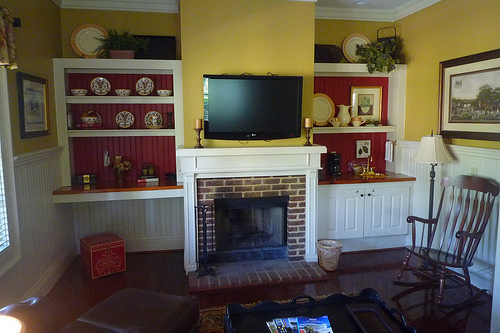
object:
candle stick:
[193, 127, 205, 148]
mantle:
[175, 144, 327, 179]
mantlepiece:
[175, 144, 327, 273]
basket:
[376, 26, 397, 63]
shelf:
[311, 47, 417, 185]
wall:
[386, 0, 499, 155]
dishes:
[62, 67, 176, 131]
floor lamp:
[410, 129, 455, 275]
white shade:
[410, 135, 454, 164]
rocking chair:
[397, 174, 499, 310]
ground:
[410, 134, 454, 163]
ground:
[400, 140, 430, 167]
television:
[203, 74, 304, 140]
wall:
[180, 0, 315, 190]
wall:
[401, 137, 500, 310]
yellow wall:
[186, 7, 306, 68]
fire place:
[196, 175, 306, 263]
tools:
[194, 203, 217, 279]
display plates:
[63, 67, 176, 131]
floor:
[0, 245, 500, 332]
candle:
[303, 117, 313, 147]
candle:
[193, 118, 204, 149]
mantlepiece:
[184, 143, 328, 274]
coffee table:
[224, 288, 418, 333]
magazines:
[264, 321, 283, 333]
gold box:
[79, 232, 127, 279]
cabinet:
[317, 181, 415, 240]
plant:
[355, 38, 401, 75]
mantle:
[175, 143, 325, 150]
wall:
[309, 0, 500, 272]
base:
[418, 163, 438, 269]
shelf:
[53, 180, 183, 203]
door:
[317, 188, 365, 240]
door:
[364, 186, 410, 238]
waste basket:
[317, 239, 343, 271]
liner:
[317, 240, 343, 272]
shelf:
[65, 95, 174, 104]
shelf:
[68, 129, 176, 137]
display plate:
[90, 77, 112, 96]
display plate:
[136, 77, 155, 96]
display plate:
[80, 110, 101, 127]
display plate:
[115, 110, 134, 129]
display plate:
[144, 111, 164, 129]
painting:
[435, 48, 500, 142]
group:
[263, 315, 337, 333]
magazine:
[265, 319, 275, 332]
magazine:
[273, 316, 285, 332]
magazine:
[280, 316, 292, 332]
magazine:
[287, 316, 299, 331]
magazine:
[291, 315, 334, 333]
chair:
[392, 175, 499, 307]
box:
[80, 233, 127, 279]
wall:
[205, 17, 293, 62]